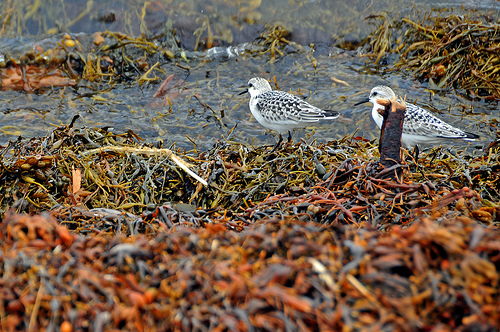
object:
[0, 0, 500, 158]
water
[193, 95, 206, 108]
reed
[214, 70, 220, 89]
reed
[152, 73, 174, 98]
reed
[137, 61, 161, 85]
reed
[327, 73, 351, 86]
reed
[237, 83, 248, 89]
beak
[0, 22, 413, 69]
snake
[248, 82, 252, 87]
eye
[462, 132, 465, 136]
feathers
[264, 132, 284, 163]
legs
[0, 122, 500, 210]
seaweed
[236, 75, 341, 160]
birds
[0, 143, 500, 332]
ground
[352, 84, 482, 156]
bird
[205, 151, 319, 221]
stuff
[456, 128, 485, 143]
feather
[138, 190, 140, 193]
twigs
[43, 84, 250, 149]
water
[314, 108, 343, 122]
tail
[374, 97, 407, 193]
stick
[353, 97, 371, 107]
beak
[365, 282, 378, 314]
plants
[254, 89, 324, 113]
back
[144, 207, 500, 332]
seaweed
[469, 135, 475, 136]
feathers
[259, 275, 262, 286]
leaves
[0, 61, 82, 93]
stump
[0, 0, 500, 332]
grass